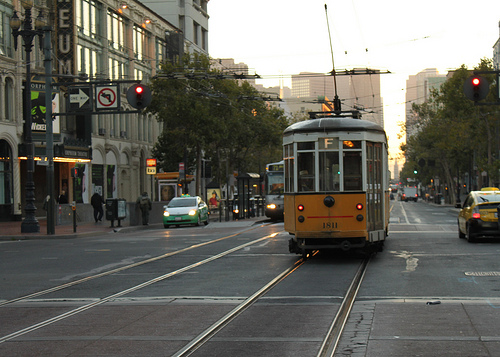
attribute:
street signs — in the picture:
[66, 87, 91, 109]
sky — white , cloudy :
[355, 14, 435, 53]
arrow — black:
[97, 84, 122, 112]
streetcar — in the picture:
[284, 113, 386, 250]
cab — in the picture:
[456, 186, 498, 241]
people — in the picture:
[104, 196, 124, 231]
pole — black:
[14, 52, 46, 237]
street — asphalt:
[21, 239, 498, 344]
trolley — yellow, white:
[273, 106, 403, 268]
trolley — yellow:
[281, 107, 388, 254]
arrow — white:
[64, 85, 97, 112]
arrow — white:
[391, 245, 433, 290]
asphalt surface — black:
[0, 238, 499, 294]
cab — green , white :
[147, 178, 252, 248]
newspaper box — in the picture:
[101, 195, 129, 221]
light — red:
[354, 200, 368, 214]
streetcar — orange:
[278, 112, 392, 256]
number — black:
[316, 217, 350, 232]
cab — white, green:
[159, 187, 210, 237]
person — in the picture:
[86, 189, 110, 227]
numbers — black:
[316, 218, 342, 230]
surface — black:
[297, 266, 340, 295]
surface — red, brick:
[75, 221, 95, 231]